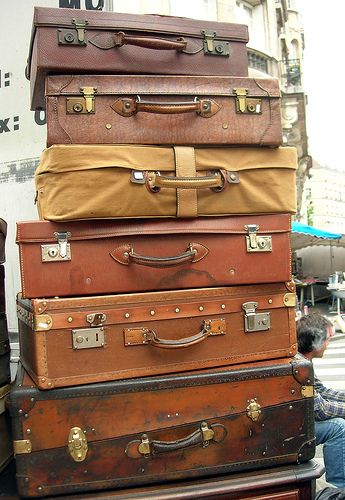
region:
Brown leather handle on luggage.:
[143, 422, 209, 462]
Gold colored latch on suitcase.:
[65, 423, 90, 461]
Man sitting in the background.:
[294, 306, 343, 495]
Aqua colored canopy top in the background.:
[289, 218, 342, 251]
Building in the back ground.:
[310, 150, 343, 231]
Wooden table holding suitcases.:
[36, 452, 325, 498]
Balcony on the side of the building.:
[232, 0, 274, 76]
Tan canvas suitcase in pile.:
[31, 142, 300, 224]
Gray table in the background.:
[294, 270, 323, 306]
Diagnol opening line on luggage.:
[12, 389, 312, 462]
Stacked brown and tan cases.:
[11, 3, 296, 492]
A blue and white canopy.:
[289, 215, 339, 239]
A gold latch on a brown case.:
[65, 425, 88, 462]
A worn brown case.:
[15, 386, 301, 493]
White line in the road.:
[306, 337, 342, 406]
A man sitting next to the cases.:
[294, 311, 343, 486]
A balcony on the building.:
[276, 52, 299, 88]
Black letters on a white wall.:
[0, 0, 110, 360]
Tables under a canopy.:
[290, 226, 341, 313]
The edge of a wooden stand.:
[5, 457, 326, 498]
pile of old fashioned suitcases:
[16, 7, 294, 477]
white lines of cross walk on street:
[317, 333, 343, 386]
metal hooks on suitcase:
[64, 318, 112, 358]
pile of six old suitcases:
[18, 9, 290, 492]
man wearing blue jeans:
[286, 314, 341, 471]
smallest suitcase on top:
[22, 16, 260, 87]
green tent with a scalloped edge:
[282, 217, 340, 241]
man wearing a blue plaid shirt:
[308, 382, 337, 411]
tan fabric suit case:
[42, 143, 293, 218]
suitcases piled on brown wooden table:
[206, 464, 324, 495]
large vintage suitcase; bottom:
[15, 374, 319, 487]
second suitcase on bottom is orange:
[21, 290, 297, 377]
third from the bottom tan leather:
[14, 214, 294, 290]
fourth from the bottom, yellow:
[35, 142, 296, 217]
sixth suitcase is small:
[30, 8, 256, 73]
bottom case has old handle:
[124, 421, 229, 453]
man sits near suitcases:
[302, 314, 342, 486]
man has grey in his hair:
[296, 315, 326, 349]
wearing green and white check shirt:
[313, 383, 342, 419]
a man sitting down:
[300, 318, 329, 361]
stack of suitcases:
[27, 132, 326, 491]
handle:
[153, 328, 205, 358]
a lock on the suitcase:
[63, 312, 119, 353]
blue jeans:
[319, 420, 343, 476]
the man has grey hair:
[311, 334, 324, 349]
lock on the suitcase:
[41, 235, 85, 268]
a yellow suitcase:
[58, 151, 289, 208]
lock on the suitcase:
[239, 395, 266, 421]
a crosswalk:
[327, 347, 344, 375]